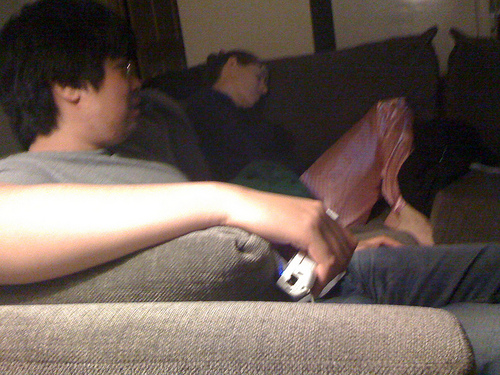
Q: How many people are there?
A: Two.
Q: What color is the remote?
A: White.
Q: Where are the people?
A: On the sofa.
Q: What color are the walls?
A: White.